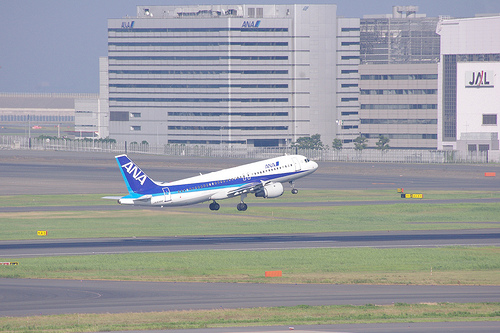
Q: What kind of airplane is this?
A: Passenger.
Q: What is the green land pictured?
A: Grass.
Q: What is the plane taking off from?
A: Runway.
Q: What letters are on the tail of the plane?
A: ANA.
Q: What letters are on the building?
A: JAL.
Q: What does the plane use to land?
A: Wheels.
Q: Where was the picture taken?
A: At a airport.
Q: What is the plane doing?
A: Taking off.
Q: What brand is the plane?
A: ANA.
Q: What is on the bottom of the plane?
A: Landing gear.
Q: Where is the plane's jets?
A: On wings.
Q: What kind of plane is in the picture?
A: Passenger plane.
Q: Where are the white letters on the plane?
A: On tail.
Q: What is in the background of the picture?
A: Buildings.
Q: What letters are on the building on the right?
A: JAL.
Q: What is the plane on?
A: Landing strip.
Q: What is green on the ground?
A: Grass.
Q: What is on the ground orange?
A: Cones.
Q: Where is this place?
A: An airport.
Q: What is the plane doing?
A: Taking off.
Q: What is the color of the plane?
A: White with blue stripes.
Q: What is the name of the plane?
A: ANA.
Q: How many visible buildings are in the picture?
A: Four.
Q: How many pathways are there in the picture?
A: Four.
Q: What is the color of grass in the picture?
A: Green.